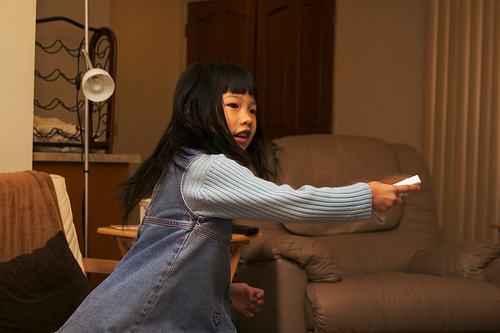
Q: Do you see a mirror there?
A: No, there are no mirrors.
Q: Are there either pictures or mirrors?
A: No, there are no mirrors or pictures.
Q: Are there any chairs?
A: Yes, there is a chair.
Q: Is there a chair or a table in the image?
A: Yes, there is a chair.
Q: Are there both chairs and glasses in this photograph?
A: No, there is a chair but no glasses.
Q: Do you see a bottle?
A: No, there are no bottles.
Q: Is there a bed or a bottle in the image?
A: No, there are no bottles or beds.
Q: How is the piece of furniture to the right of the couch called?
A: The piece of furniture is a chair.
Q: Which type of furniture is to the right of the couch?
A: The piece of furniture is a chair.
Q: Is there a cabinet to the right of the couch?
A: No, there is a chair to the right of the couch.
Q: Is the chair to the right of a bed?
A: No, the chair is to the right of the couch.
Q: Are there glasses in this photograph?
A: No, there are no glasses.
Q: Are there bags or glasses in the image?
A: No, there are no glasses or bags.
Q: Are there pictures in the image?
A: No, there are no pictures.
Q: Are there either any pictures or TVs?
A: No, there are no pictures or tvs.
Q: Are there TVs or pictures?
A: No, there are no pictures or tvs.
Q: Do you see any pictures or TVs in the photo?
A: No, there are no pictures or tvs.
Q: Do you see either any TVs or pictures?
A: No, there are no pictures or tvs.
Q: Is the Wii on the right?
A: Yes, the Wii is on the right of the image.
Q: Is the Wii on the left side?
A: No, the Wii is on the right of the image.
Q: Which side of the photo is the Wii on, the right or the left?
A: The Wii is on the right of the image.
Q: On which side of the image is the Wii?
A: The Wii is on the right of the image.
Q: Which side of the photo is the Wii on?
A: The Wii is on the right of the image.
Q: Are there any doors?
A: Yes, there are doors.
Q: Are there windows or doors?
A: Yes, there are doors.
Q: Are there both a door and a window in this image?
A: Yes, there are both a door and a window.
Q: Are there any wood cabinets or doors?
A: Yes, there are wood doors.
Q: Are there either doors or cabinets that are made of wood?
A: Yes, the doors are made of wood.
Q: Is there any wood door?
A: Yes, there are doors that are made of wood.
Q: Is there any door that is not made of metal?
A: Yes, there are doors that are made of wood.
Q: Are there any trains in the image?
A: No, there are no trains.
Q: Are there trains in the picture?
A: No, there are no trains.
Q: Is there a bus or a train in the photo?
A: No, there are no trains or buses.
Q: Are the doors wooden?
A: Yes, the doors are wooden.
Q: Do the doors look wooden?
A: Yes, the doors are wooden.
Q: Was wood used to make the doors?
A: Yes, the doors are made of wood.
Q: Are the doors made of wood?
A: Yes, the doors are made of wood.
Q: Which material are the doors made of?
A: The doors are made of wood.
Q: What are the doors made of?
A: The doors are made of wood.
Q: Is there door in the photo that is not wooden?
A: No, there are doors but they are wooden.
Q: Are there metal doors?
A: No, there are doors but they are made of wood.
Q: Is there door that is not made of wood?
A: No, there are doors but they are made of wood.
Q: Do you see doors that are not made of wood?
A: No, there are doors but they are made of wood.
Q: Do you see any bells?
A: No, there are no bells.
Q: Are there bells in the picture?
A: No, there are no bells.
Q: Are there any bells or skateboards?
A: No, there are no bells or skateboards.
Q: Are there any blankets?
A: Yes, there is a blanket.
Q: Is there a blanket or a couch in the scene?
A: Yes, there is a blanket.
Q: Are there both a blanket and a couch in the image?
A: Yes, there are both a blanket and a couch.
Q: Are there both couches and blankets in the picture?
A: Yes, there are both a blanket and a couch.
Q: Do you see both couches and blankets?
A: Yes, there are both a blanket and a couch.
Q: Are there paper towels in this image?
A: No, there are no paper towels.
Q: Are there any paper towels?
A: No, there are no paper towels.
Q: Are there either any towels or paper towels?
A: No, there are no paper towels or towels.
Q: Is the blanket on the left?
A: Yes, the blanket is on the left of the image.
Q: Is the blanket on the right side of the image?
A: No, the blanket is on the left of the image.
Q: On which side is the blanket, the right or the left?
A: The blanket is on the left of the image.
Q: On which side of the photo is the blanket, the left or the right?
A: The blanket is on the left of the image.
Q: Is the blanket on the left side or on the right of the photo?
A: The blanket is on the left of the image.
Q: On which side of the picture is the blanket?
A: The blanket is on the left of the image.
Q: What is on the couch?
A: The blanket is on the couch.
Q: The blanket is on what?
A: The blanket is on the couch.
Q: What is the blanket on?
A: The blanket is on the couch.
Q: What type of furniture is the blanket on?
A: The blanket is on the couch.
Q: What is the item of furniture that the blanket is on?
A: The piece of furniture is a couch.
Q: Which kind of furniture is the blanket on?
A: The blanket is on the couch.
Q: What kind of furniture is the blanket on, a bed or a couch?
A: The blanket is on a couch.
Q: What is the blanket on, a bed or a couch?
A: The blanket is on a couch.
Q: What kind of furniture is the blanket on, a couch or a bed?
A: The blanket is on a couch.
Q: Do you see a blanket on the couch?
A: Yes, there is a blanket on the couch.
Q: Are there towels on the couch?
A: No, there is a blanket on the couch.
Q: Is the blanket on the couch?
A: Yes, the blanket is on the couch.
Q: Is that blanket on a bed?
A: No, the blanket is on the couch.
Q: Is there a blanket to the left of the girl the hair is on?
A: Yes, there is a blanket to the left of the girl.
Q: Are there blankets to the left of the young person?
A: Yes, there is a blanket to the left of the girl.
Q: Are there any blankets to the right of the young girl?
A: No, the blanket is to the left of the girl.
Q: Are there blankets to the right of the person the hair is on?
A: No, the blanket is to the left of the girl.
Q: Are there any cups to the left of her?
A: No, there is a blanket to the left of the girl.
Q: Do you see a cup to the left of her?
A: No, there is a blanket to the left of the girl.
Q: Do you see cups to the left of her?
A: No, there is a blanket to the left of the girl.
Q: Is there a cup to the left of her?
A: No, there is a blanket to the left of the girl.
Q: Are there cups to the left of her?
A: No, there is a blanket to the left of the girl.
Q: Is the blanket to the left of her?
A: Yes, the blanket is to the left of the girl.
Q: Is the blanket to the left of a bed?
A: No, the blanket is to the left of the girl.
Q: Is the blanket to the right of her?
A: No, the blanket is to the left of the girl.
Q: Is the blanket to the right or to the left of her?
A: The blanket is to the left of the girl.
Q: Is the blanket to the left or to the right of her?
A: The blanket is to the left of the girl.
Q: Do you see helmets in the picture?
A: No, there are no helmets.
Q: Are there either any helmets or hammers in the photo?
A: No, there are no helmets or hammers.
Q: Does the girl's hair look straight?
A: Yes, the hair is straight.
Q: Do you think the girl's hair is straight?
A: Yes, the hair is straight.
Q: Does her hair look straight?
A: Yes, the hair is straight.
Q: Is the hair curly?
A: No, the hair is straight.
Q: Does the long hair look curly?
A: No, the hair is straight.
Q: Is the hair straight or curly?
A: The hair is straight.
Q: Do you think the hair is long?
A: Yes, the hair is long.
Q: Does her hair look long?
A: Yes, the hair is long.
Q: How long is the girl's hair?
A: The hair is long.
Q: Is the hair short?
A: No, the hair is long.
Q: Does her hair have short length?
A: No, the hair is long.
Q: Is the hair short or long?
A: The hair is long.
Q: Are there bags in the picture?
A: No, there are no bags.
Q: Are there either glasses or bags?
A: No, there are no bags or glasses.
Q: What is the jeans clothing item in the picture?
A: The clothing item is a dress.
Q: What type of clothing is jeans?
A: The clothing is a dress.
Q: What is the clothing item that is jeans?
A: The clothing item is a dress.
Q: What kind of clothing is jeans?
A: The clothing is a dress.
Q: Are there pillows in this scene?
A: Yes, there is a pillow.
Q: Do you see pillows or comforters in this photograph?
A: Yes, there is a pillow.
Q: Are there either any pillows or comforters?
A: Yes, there is a pillow.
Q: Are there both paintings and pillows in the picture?
A: No, there is a pillow but no paintings.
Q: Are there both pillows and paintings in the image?
A: No, there is a pillow but no paintings.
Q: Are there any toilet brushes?
A: No, there are no toilet brushes.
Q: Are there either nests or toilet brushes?
A: No, there are no toilet brushes or nests.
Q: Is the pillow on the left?
A: Yes, the pillow is on the left of the image.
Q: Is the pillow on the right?
A: No, the pillow is on the left of the image.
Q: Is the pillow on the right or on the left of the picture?
A: The pillow is on the left of the image.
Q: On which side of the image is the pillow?
A: The pillow is on the left of the image.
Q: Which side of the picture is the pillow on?
A: The pillow is on the left of the image.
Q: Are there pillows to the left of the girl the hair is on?
A: Yes, there is a pillow to the left of the girl.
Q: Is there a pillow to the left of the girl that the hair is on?
A: Yes, there is a pillow to the left of the girl.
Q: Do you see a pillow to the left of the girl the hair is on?
A: Yes, there is a pillow to the left of the girl.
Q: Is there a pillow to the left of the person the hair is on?
A: Yes, there is a pillow to the left of the girl.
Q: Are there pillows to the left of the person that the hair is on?
A: Yes, there is a pillow to the left of the girl.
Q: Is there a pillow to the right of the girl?
A: No, the pillow is to the left of the girl.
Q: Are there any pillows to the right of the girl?
A: No, the pillow is to the left of the girl.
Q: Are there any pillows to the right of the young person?
A: No, the pillow is to the left of the girl.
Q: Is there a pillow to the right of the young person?
A: No, the pillow is to the left of the girl.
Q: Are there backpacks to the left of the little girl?
A: No, there is a pillow to the left of the girl.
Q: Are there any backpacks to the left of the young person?
A: No, there is a pillow to the left of the girl.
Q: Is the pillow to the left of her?
A: Yes, the pillow is to the left of the girl.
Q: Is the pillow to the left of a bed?
A: No, the pillow is to the left of the girl.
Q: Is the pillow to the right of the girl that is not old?
A: No, the pillow is to the left of the girl.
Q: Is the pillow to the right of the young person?
A: No, the pillow is to the left of the girl.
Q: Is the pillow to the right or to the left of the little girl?
A: The pillow is to the left of the girl.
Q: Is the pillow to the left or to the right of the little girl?
A: The pillow is to the left of the girl.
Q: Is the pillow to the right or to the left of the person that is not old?
A: The pillow is to the left of the girl.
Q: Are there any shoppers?
A: No, there are no shoppers.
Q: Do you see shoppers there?
A: No, there are no shoppers.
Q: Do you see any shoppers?
A: No, there are no shoppers.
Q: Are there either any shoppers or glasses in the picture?
A: No, there are no shoppers or glasses.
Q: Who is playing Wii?
A: The girl is playing wii.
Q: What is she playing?
A: The girl is playing wii.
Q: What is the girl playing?
A: The girl is playing wii.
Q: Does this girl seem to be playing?
A: Yes, the girl is playing.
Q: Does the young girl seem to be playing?
A: Yes, the girl is playing.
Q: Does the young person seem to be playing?
A: Yes, the girl is playing.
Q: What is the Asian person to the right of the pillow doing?
A: The girl is playing.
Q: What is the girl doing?
A: The girl is playing.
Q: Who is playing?
A: The girl is playing.